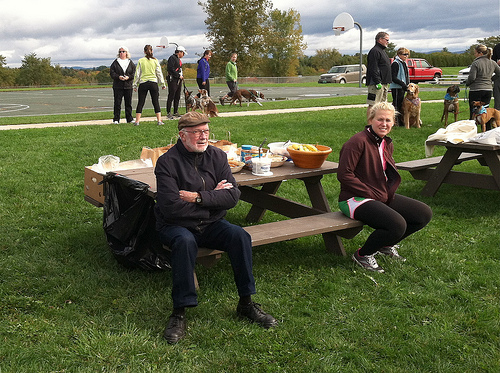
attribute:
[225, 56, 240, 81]
jacket — green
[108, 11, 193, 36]
clouds — gray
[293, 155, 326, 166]
bowl — orange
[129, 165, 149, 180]
table — picnic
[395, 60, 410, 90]
vest — blue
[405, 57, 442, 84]
truck — red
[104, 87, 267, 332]
gentleman — older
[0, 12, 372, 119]
basketball court — in background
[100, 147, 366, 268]
picnic table — wood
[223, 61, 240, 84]
shirt — green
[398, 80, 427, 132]
retreiver — golden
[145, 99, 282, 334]
man — old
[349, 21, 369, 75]
pole — grey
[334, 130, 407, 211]
jacket — black